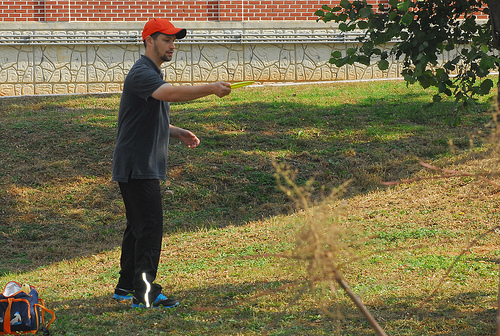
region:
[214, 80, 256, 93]
yellow frisbe in mans hand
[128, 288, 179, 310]
blue and black shoes on mans feet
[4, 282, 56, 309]
orange and blue bag on ground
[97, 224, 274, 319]
green and brown grass under mans feet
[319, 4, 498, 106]
green leaves of tree right of man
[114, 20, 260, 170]
man throwing frisbee in orange hat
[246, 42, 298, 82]
cement wall to look like stone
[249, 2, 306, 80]
red brick over fake stone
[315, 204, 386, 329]
dead tree limb in middle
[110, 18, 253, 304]
man throwing frisbee in black pants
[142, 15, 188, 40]
an orange sun visor cap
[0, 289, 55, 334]
a blue and orange carry bag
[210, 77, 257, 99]
a yellow Frisbee in a man's hand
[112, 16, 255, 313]
a man throwing a yellow Frisbee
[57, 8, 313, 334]
a man in an orange hat playing Frisbee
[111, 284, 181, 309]
black and blue athletic shoes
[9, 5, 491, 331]
a man playing Frisbee in a field beside a brick building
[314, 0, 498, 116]
green leaves on branches of tree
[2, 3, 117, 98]
the side of a red brick building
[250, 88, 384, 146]
green and brown grass on the ground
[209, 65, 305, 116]
The man is about to throw a frisbee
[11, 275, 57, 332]
The bag has orange straps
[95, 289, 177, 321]
The shoes are blue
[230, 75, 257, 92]
the frisbee is green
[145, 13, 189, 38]
The hat is orange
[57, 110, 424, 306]
In a grassy field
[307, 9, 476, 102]
There are tree leaves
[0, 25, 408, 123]
There is a building behind him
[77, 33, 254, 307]
Man is playing frisbee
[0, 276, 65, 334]
The bag is on the ground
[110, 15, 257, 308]
a man playing frisbee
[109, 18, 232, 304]
a man standing in grass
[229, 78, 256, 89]
a round yellow frisbee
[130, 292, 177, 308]
a blue and black shoe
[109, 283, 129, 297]
a blue and black shoe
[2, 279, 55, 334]
a blue and orange duffel bag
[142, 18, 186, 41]
an orange men's hat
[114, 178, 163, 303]
a pair of black pants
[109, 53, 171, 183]
a grey polo shirt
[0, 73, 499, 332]
a green field of grass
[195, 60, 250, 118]
man holding a yellow frisbee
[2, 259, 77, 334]
bag on the ground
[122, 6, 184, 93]
orange cap on the man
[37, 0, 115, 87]
brick and stone wall behind the man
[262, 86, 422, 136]
shadow on the ground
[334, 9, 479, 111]
leaves on a tree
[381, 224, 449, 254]
green grass on the ground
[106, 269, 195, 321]
shoes on feet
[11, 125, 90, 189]
patches of dirt in the grass